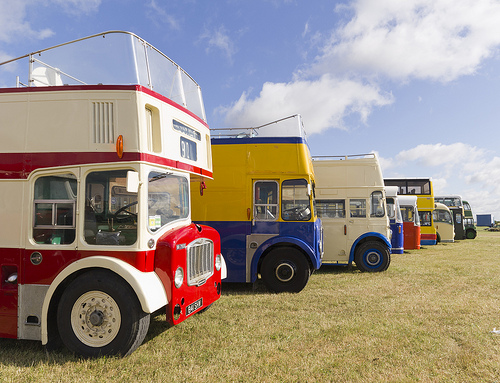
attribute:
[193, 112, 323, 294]
rv — yellow, blue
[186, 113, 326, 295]
bus — blue, yellow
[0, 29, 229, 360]
buses — parked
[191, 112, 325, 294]
buses — parked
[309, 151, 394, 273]
buses — parked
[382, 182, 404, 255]
buses — parked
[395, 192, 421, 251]
buses — parked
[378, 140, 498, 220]
clouds — white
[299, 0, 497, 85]
clouds — white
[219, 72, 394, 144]
clouds — white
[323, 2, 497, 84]
clouds — white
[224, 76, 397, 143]
clouds — white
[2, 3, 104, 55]
clouds — white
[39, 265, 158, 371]
wheel — part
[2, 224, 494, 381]
lawn — part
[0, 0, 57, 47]
clouds — white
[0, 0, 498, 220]
sky — blue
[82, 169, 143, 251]
window — part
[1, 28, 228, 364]
truck — white, red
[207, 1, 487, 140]
cloud — white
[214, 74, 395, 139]
cloud — white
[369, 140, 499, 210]
cloud — white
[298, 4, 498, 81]
cloud — white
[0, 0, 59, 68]
cloud — white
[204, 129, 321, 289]
rv — blue, yellow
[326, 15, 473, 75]
clouds — white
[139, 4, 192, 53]
clouds — white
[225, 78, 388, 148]
cloud — white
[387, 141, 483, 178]
cloud — white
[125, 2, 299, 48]
sky — blue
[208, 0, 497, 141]
clouds — white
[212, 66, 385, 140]
clouds — white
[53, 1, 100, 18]
clouds — white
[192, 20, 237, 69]
clouds — white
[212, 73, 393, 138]
clouds — white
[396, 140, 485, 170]
clouds — white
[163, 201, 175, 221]
window — part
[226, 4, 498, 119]
clouds — white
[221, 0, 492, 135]
clouds — white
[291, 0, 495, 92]
clouds — white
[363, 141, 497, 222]
clouds — white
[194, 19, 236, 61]
clouds — white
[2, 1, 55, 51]
clouds — white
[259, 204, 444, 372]
lawn — part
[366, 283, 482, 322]
field — part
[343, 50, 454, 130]
clouds — white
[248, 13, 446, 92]
sky — blue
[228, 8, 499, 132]
clouds — white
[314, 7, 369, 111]
clouds — white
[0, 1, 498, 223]
clouds — white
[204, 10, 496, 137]
sky — blue